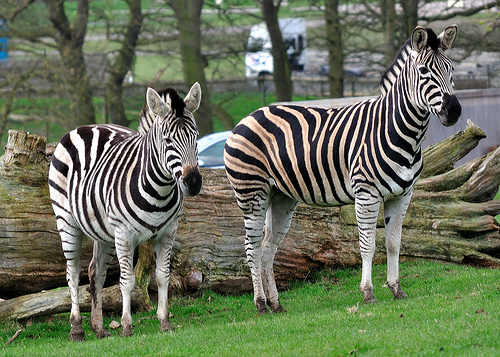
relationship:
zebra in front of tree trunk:
[221, 25, 461, 313] [2, 126, 496, 336]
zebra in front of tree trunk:
[39, 80, 205, 342] [2, 126, 496, 336]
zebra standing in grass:
[221, 25, 461, 313] [0, 0, 499, 356]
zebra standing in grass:
[39, 80, 205, 342] [0, 0, 499, 356]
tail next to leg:
[87, 244, 100, 311] [86, 236, 111, 341]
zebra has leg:
[39, 80, 205, 342] [86, 236, 111, 341]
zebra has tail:
[39, 80, 205, 342] [87, 244, 100, 311]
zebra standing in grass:
[221, 25, 461, 313] [0, 256, 499, 354]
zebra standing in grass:
[39, 80, 205, 342] [0, 256, 499, 354]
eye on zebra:
[162, 135, 173, 145] [39, 80, 205, 342]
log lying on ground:
[0, 111, 499, 303] [5, 245, 499, 353]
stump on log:
[6, 125, 61, 166] [0, 141, 499, 309]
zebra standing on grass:
[221, 25, 461, 313] [0, 256, 499, 354]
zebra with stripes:
[39, 80, 205, 342] [87, 160, 119, 227]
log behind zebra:
[0, 111, 499, 303] [221, 25, 461, 313]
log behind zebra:
[0, 111, 499, 303] [39, 80, 205, 342]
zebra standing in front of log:
[221, 25, 461, 313] [0, 141, 499, 309]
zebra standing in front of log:
[39, 80, 205, 342] [0, 141, 499, 309]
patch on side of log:
[0, 255, 499, 355] [0, 117, 499, 320]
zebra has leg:
[221, 25, 461, 313] [258, 190, 298, 312]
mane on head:
[421, 20, 440, 57] [369, 20, 479, 144]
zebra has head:
[221, 25, 461, 313] [369, 20, 479, 144]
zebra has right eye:
[221, 25, 461, 313] [416, 63, 431, 76]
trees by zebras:
[37, 15, 278, 88] [48, 98, 439, 285]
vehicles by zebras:
[228, 9, 384, 73] [48, 98, 439, 285]